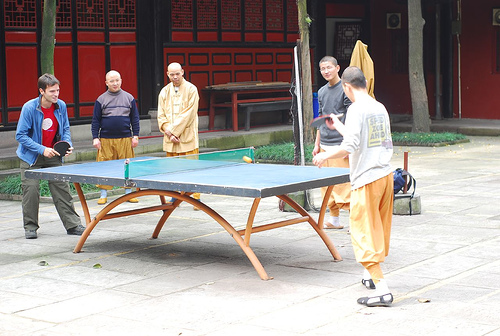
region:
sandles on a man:
[356, 294, 398, 304]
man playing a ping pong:
[341, 66, 401, 307]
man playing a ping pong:
[18, 71, 72, 173]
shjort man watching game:
[91, 72, 140, 157]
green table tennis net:
[120, 148, 263, 177]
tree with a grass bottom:
[384, 0, 468, 142]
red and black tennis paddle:
[49, 141, 74, 156]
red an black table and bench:
[209, 83, 297, 129]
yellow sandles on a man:
[96, 194, 107, 204]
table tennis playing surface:
[75, 151, 350, 265]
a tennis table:
[194, 160, 302, 196]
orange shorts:
[350, 193, 390, 260]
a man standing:
[91, 73, 143, 159]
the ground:
[44, 265, 157, 322]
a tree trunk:
[405, 37, 435, 135]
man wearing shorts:
[350, 194, 384, 258]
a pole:
[287, 49, 312, 161]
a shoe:
[22, 227, 40, 240]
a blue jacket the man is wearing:
[12, 110, 37, 141]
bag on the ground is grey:
[395, 195, 418, 212]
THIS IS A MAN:
[15, 73, 87, 253]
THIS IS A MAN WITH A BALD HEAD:
[89, 69, 140, 206]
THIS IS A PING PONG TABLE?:
[22, 146, 365, 281]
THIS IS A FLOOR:
[3, 140, 496, 335]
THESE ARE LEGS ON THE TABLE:
[72, 183, 343, 268]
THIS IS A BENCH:
[203, 78, 298, 130]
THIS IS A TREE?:
[405, 23, 432, 134]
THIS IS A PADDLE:
[53, 138, 71, 160]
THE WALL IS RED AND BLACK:
[0, 0, 310, 130]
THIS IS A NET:
[122, 145, 264, 177]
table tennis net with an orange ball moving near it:
[121, 143, 264, 185]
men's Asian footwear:
[353, 266, 399, 311]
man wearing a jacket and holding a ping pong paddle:
[11, 63, 88, 244]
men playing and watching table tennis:
[1, 1, 499, 335]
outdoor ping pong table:
[23, 142, 355, 293]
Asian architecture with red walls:
[1, 0, 499, 127]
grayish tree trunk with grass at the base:
[393, 0, 464, 146]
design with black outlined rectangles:
[187, 47, 275, 68]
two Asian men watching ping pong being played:
[84, 50, 273, 284]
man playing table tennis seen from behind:
[225, 65, 416, 311]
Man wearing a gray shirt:
[327, 63, 418, 319]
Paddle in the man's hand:
[311, 106, 345, 128]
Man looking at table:
[150, 61, 202, 161]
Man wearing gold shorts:
[90, 67, 144, 187]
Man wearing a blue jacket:
[13, 66, 87, 239]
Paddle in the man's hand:
[45, 137, 72, 162]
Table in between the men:
[23, 144, 354, 281]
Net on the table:
[115, 141, 267, 181]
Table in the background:
[190, 59, 307, 134]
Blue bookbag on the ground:
[387, 154, 422, 205]